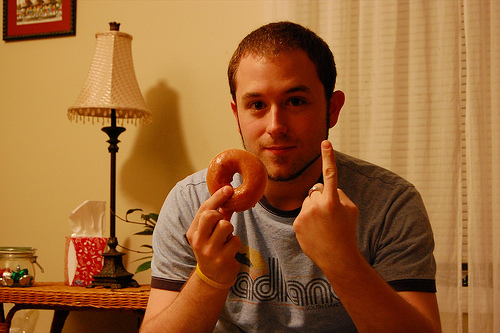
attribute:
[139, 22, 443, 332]
man — married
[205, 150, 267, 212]
donut — glazed, brown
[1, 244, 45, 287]
jar — clear, silver, glass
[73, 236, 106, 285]
box of tissue — red, white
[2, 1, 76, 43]
picture — red, black, white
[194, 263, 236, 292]
bracelet — yellow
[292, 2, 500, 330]
curtains — white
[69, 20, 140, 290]
lamp — tall, beige, brown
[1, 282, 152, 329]
table — wicker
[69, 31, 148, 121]
lamp shade — white, tan, beige, fringed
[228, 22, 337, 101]
hair — short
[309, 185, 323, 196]
ring — silver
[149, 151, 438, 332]
shirt — brown, blue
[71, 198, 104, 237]
tissue — white